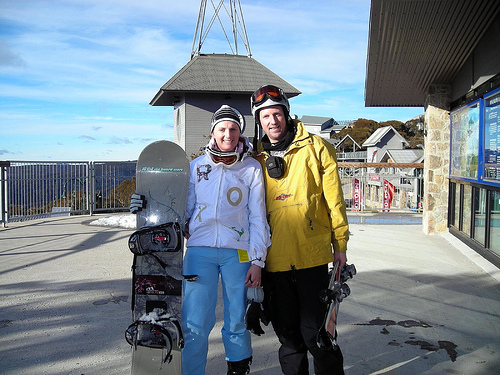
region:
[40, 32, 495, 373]
young couple posing for picture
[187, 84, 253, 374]
young white woman wearing snow gear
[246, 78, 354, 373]
middle-aged white man wearing snow gear and yellow jacket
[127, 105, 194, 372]
gloved hand holding gray snowboard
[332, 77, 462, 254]
background houses and sky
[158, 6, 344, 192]
faces against cell tower and sky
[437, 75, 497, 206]
a schedule list and screen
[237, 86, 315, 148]
white man with red glasses over white helmet on head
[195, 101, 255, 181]
woman with white glasses and white hat wearing white heavy coat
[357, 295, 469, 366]
dark stain on gray pavement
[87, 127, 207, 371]
a gray snowboard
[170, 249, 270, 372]
pair of blue snowpants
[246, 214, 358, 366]
pair of black snow pants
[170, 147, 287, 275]
a blue snow jacket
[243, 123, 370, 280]
a yellow snow jacket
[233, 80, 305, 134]
a white snow helmet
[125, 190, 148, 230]
a blue snow glove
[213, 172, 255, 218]
the gold letter O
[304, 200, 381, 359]
a set of skis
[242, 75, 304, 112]
a pair of black goggles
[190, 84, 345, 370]
a man and a woman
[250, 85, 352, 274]
man in a yellow jacket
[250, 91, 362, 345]
man carrying a pair of skis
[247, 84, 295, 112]
ski goggles with red tinting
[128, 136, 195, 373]
grey snow board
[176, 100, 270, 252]
woman in a white ski jacket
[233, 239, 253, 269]
yellow ski lift ticket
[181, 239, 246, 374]
light blue ski pants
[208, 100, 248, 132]
black and white striped ski hat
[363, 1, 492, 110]
roof overhang of nearby building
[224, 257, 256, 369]
the leg of a person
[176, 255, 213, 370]
the leg of a person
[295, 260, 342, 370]
the leg of a person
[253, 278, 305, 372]
the leg of a person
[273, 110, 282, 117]
the eye of a person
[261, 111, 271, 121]
the eye of a person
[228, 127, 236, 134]
the eye of a person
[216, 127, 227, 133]
the eye of a person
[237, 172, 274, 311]
the hand of a person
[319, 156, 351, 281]
the hand of a person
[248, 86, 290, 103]
black and red goggles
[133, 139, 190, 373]
black snowboard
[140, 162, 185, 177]
green print on the black board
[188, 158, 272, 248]
colorful prints on the white jacket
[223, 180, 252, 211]
circle design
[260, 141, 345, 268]
yellow jacket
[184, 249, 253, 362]
light blue pants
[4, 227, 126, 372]
gray ground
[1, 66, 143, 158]
white clouds in the light blue sky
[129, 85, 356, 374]
man and woman posing with a snowboard